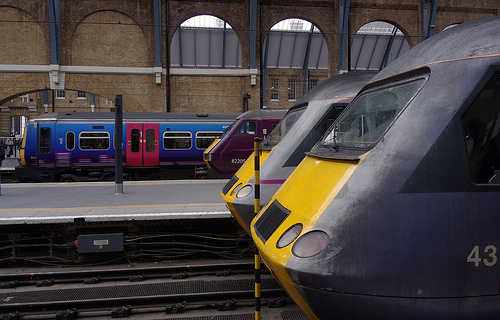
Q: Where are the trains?
A: On the tracks.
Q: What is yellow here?
A: Trains.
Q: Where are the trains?
A: In the station.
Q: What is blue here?
A: A train.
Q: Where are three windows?
A: Top of building.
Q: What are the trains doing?
A: Parking.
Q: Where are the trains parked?
A: At the station.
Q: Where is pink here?
A: On the door.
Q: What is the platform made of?
A: Cement.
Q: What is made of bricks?
A: The wall.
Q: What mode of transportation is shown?
A: Trains.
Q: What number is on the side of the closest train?
A: 43.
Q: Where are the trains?
A: Tracks.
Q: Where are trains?
A: On train tracks.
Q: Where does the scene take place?
A: At a train station.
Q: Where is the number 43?
A: On side of the train.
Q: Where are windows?
A: On the trains.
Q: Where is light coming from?
A: Windows.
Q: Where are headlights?
A: On front of the train.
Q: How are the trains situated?
A: Next to each other.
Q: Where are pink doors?
A: On side of the train.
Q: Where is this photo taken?
A: At a subway station.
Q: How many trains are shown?
A: 4.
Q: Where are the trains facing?
A: Left.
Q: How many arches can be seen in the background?
A: Six.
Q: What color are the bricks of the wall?
A: Brown.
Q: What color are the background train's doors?
A: Red.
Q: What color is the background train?
A: Blue.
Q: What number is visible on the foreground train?
A: 43.